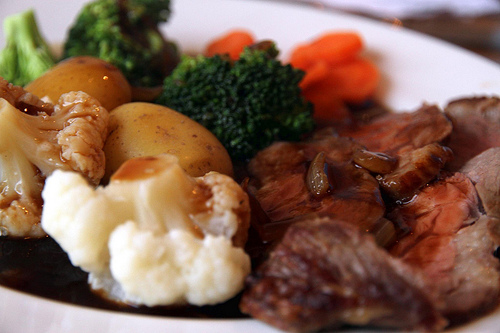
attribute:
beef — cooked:
[254, 214, 452, 330]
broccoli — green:
[0, 8, 60, 89]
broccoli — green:
[60, 1, 180, 91]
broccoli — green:
[164, 36, 311, 159]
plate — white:
[1, 1, 496, 329]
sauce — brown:
[4, 235, 181, 308]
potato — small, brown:
[17, 51, 128, 117]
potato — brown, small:
[102, 98, 234, 185]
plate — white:
[214, 9, 437, 46]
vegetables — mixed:
[3, 6, 295, 307]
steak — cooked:
[263, 139, 394, 226]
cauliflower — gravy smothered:
[0, 89, 109, 240]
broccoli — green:
[174, 44, 316, 147]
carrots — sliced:
[205, 27, 381, 129]